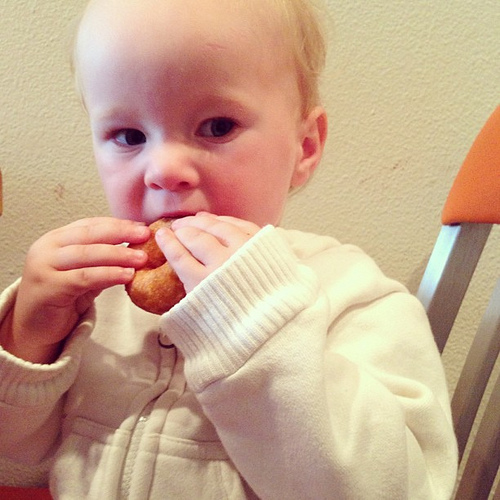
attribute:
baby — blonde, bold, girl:
[2, 1, 457, 499]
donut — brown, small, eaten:
[122, 217, 187, 309]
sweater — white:
[0, 226, 459, 499]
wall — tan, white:
[2, 3, 496, 500]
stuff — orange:
[439, 102, 499, 225]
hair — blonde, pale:
[268, 1, 328, 117]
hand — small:
[154, 210, 262, 293]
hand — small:
[24, 213, 150, 309]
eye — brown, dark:
[193, 117, 239, 138]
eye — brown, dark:
[110, 127, 147, 146]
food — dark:
[53, 184, 67, 196]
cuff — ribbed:
[161, 224, 318, 396]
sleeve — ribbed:
[154, 225, 457, 500]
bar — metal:
[417, 223, 492, 352]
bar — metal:
[450, 276, 499, 464]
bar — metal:
[454, 371, 499, 498]